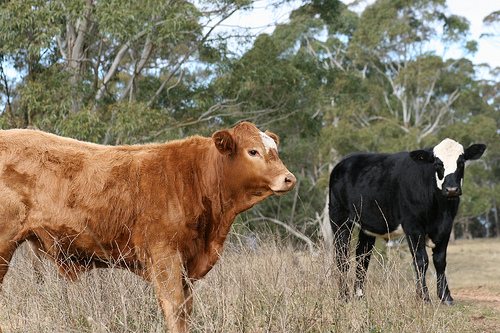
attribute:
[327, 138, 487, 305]
cow — black, tall, posing, photographed, large, looking, white, standing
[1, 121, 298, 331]
cow — brown, tall, photographed, red, large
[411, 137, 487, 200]
head — white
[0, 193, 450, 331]
grass — tall, brown, patch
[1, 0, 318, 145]
tree — green, tall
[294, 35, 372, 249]
tree — green, tall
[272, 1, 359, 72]
tree — green, tall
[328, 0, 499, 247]
tree — green, tall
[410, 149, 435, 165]
ear — black, pointed outward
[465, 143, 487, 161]
ear — black, pointed outward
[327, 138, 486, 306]
coat — silky, black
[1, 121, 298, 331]
coat — ruffled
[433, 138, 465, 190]
patch — white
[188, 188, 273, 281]
bit — fleshy